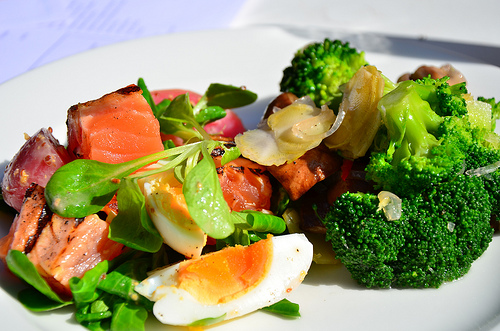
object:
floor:
[30, 15, 126, 30]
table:
[0, 0, 496, 80]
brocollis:
[280, 38, 395, 108]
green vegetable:
[2, 250, 153, 331]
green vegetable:
[38, 79, 286, 254]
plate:
[0, 26, 498, 331]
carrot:
[63, 84, 166, 166]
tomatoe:
[213, 157, 269, 212]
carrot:
[13, 188, 114, 296]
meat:
[71, 86, 159, 165]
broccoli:
[320, 175, 495, 289]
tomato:
[202, 112, 242, 139]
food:
[0, 38, 500, 331]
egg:
[134, 228, 314, 324]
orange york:
[172, 234, 267, 301]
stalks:
[375, 81, 442, 163]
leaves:
[111, 181, 156, 254]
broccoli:
[363, 72, 476, 196]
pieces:
[3, 127, 64, 209]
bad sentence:
[163, 11, 202, 46]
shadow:
[303, 262, 355, 285]